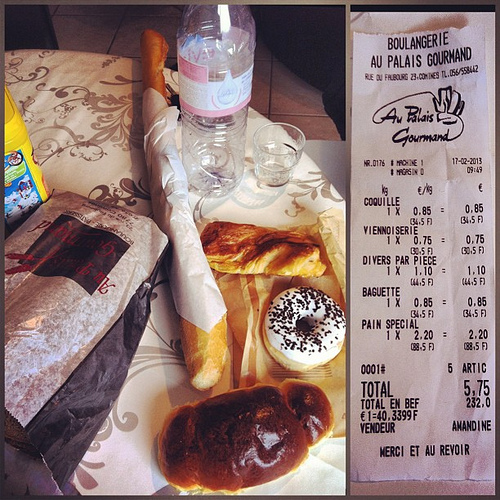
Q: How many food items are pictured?
A: Four.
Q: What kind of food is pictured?
A: Baked goods.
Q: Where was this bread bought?
A: Au Blais Gourmand.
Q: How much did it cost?
A: 5.75.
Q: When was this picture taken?
A: Daytime.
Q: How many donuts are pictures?
A: One.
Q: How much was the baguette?
A: 0.85.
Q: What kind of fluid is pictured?
A: Water.